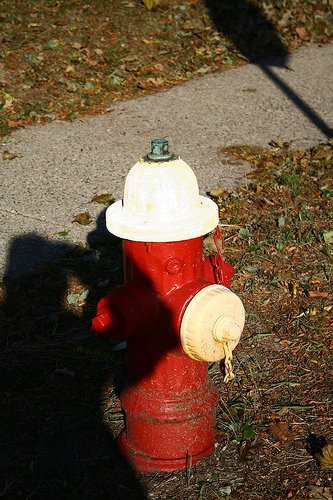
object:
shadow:
[200, 0, 332, 141]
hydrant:
[105, 138, 246, 476]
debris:
[240, 86, 256, 94]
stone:
[212, 440, 219, 449]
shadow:
[0, 198, 180, 498]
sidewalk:
[0, 41, 332, 295]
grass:
[271, 156, 307, 196]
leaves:
[0, 148, 24, 163]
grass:
[316, 181, 332, 210]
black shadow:
[199, 0, 289, 69]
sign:
[201, 0, 297, 72]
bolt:
[145, 242, 154, 255]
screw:
[165, 257, 182, 276]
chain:
[222, 341, 234, 385]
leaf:
[311, 441, 332, 469]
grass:
[0, 0, 332, 138]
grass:
[215, 358, 272, 453]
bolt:
[146, 137, 175, 163]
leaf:
[70, 210, 93, 227]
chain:
[208, 228, 224, 286]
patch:
[0, 0, 332, 499]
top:
[145, 137, 175, 163]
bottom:
[116, 423, 220, 477]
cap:
[105, 138, 219, 245]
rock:
[215, 483, 235, 496]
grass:
[101, 381, 125, 425]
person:
[0, 198, 181, 500]